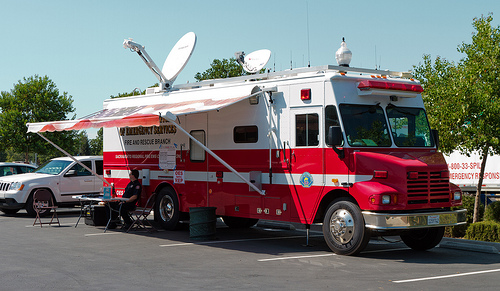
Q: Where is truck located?
A: Parking lot.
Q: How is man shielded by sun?
A: Awning.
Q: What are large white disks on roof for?
A: Satellites.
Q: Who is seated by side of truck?
A: Firefighter.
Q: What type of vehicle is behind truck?
A: Car.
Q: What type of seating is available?
A: Folding chair.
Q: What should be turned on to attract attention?
A: Siren and lights.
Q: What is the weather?
A: Clear and sunny.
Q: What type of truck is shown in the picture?
A: An ambulance.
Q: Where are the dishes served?
A: On the truck.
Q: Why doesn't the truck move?
A: The drivers are waiting for customers to come.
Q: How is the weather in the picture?
A: Sunny or clear.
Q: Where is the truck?
A: Parking lot.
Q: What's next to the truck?
A: Green tree.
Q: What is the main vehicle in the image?
A: A truck.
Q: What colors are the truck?
A: Red and white.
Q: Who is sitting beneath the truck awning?
A: The person.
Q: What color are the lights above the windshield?
A: Red.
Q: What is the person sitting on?
A: A chair.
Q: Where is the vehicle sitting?
A: In a parking lot.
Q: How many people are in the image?
A: One.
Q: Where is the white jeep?
A: Behind the truck.